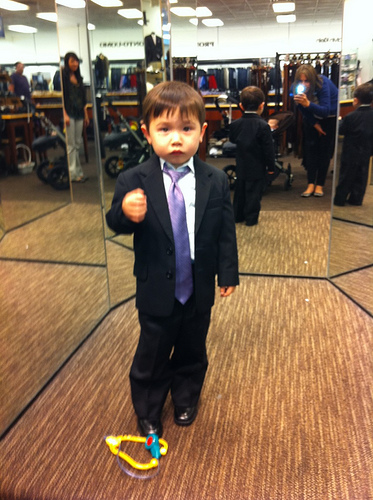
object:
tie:
[161, 164, 191, 302]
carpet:
[0, 189, 372, 500]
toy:
[104, 433, 169, 481]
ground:
[0, 208, 373, 500]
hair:
[143, 78, 204, 140]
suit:
[103, 151, 241, 424]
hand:
[122, 188, 147, 223]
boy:
[105, 78, 238, 437]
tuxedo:
[104, 155, 242, 422]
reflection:
[59, 49, 92, 184]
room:
[0, 0, 373, 500]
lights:
[271, 0, 297, 25]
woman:
[286, 62, 340, 197]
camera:
[293, 83, 307, 103]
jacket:
[105, 152, 239, 319]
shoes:
[134, 403, 165, 439]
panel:
[0, 0, 111, 455]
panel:
[83, 1, 170, 310]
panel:
[170, 0, 336, 280]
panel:
[326, 0, 373, 320]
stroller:
[213, 116, 281, 158]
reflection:
[286, 62, 337, 199]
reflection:
[230, 84, 276, 226]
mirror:
[0, 1, 373, 451]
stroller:
[105, 108, 146, 139]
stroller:
[22, 90, 71, 190]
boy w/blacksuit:
[226, 82, 276, 224]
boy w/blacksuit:
[332, 79, 372, 207]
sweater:
[297, 76, 338, 129]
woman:
[61, 53, 91, 183]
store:
[0, 0, 373, 497]